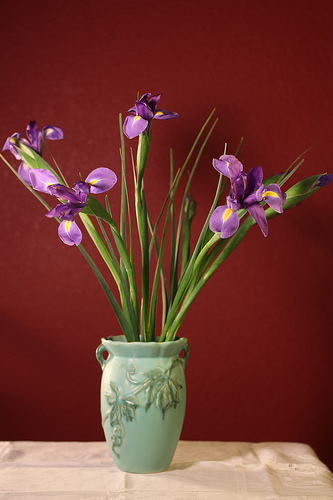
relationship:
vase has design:
[93, 333, 196, 474] [102, 362, 179, 461]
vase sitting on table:
[93, 333, 196, 474] [1, 440, 331, 500]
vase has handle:
[93, 333, 196, 474] [94, 343, 110, 367]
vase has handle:
[93, 333, 196, 474] [175, 338, 189, 360]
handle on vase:
[94, 343, 110, 367] [93, 333, 196, 474]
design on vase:
[102, 362, 179, 461] [93, 333, 196, 474]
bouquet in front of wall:
[6, 89, 321, 345] [0, 2, 331, 474]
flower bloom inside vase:
[122, 90, 178, 184] [93, 333, 196, 474]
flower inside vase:
[4, 119, 142, 343] [93, 333, 196, 474]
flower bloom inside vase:
[28, 162, 117, 250] [93, 333, 196, 474]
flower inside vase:
[260, 173, 333, 219] [93, 333, 196, 474]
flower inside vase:
[174, 171, 330, 342] [93, 333, 196, 474]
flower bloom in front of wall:
[122, 90, 178, 184] [0, 2, 331, 474]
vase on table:
[93, 333, 196, 474] [1, 440, 331, 500]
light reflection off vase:
[89, 340, 147, 475] [93, 333, 196, 474]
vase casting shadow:
[93, 333, 196, 474] [141, 431, 257, 476]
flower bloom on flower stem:
[44, 166, 123, 251] [127, 125, 158, 341]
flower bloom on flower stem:
[123, 87, 175, 140] [127, 125, 158, 341]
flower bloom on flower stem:
[44, 166, 123, 251] [81, 198, 148, 345]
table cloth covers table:
[1, 442, 331, 499] [1, 440, 331, 500]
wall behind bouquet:
[0, 2, 331, 474] [6, 89, 321, 345]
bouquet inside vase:
[6, 89, 321, 345] [93, 333, 196, 474]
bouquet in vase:
[6, 89, 321, 345] [93, 333, 196, 474]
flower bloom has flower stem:
[44, 166, 123, 251] [81, 198, 148, 345]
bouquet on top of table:
[6, 89, 321, 345] [1, 440, 331, 500]